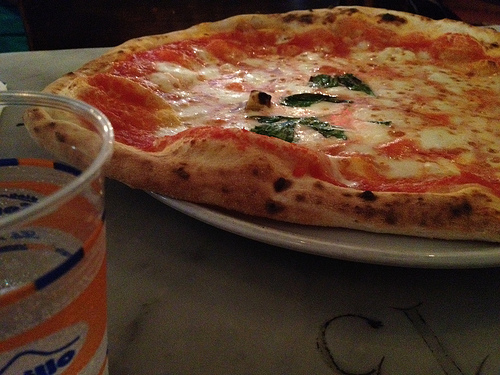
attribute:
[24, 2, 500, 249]
pizza — small, large, round, wide, cooked, ready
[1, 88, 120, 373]
cup — plastic, orange, blue, clear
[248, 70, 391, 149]
basil — laying, cooked, green, dark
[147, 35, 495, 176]
cheese — white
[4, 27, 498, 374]
table — grey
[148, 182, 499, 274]
plate — white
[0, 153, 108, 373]
soda — clear, bubbly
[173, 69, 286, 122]
mozzarella cheese — melted